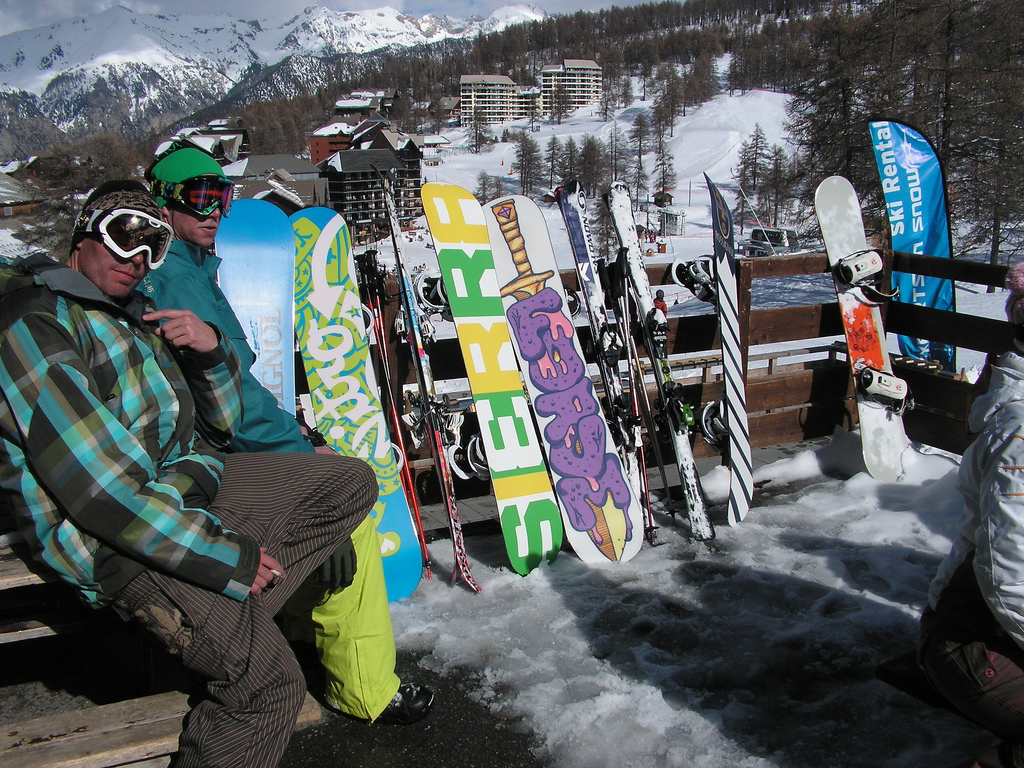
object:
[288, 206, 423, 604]
snowboard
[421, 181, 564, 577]
snowboard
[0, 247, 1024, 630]
fence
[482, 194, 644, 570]
snowboard